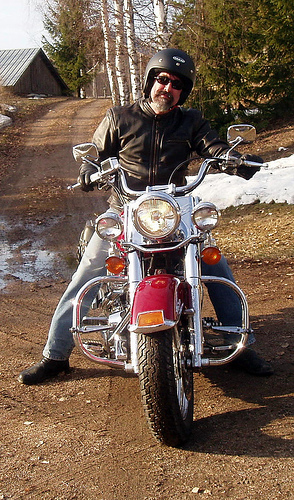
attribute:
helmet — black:
[137, 42, 204, 115]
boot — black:
[16, 353, 71, 388]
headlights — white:
[85, 199, 219, 245]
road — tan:
[0, 82, 120, 319]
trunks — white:
[95, 0, 148, 109]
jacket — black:
[81, 99, 242, 209]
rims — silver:
[174, 330, 197, 414]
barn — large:
[2, 45, 73, 96]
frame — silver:
[65, 125, 267, 371]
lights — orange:
[97, 249, 227, 276]